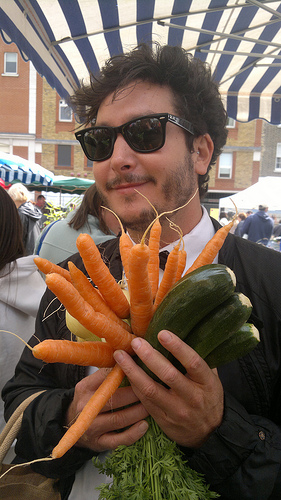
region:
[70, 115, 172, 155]
Large black sun glasses being worn and reflecting a crowd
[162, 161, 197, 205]
A patchy brown beard on a man's face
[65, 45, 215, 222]
Man with tousled brown hair and facial hair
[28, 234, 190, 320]
A group of large orange raw carrots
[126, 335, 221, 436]
Hand holding a number of different vegetables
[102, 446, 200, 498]
Leafy green heads of carrots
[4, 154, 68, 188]
White and blue canopy of a tent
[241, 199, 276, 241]
Man wearing a baseball hat and a blue sweater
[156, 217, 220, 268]
White under shirt being worn by a man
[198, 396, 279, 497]
Sleeve of a dark black jacket with a button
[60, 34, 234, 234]
the head of a man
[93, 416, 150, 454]
the finger of a man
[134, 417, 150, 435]
the finger nail of a man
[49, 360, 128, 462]
an orange carrot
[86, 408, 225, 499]
the stems of the carrots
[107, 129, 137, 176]
the nose of a man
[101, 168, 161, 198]
the mouth of a man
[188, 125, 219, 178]
the ear of a man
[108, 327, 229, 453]
the hand of a man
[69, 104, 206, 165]
a pair of sunglasses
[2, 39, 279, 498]
man holding vegetables at open air market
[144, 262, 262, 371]
green zucchinis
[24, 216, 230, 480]
fresh produce orange carrots with roots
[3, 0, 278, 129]
blue and white shade canopy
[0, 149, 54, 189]
blue and white striped canopy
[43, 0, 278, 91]
metal canopy frame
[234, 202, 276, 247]
man at outdoor market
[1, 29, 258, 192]
exterior brick wall of multistory building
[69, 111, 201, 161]
pair of sunglasses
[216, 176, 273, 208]
white shade canopy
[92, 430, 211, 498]
greens of a bunch of carrots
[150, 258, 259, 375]
three zucchinis squash in a hand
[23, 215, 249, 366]
bunch of orange carrots in a hand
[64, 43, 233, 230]
head of man with dark brown hair and beard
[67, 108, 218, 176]
dark eyeglasses on a man with a beard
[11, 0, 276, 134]
black and white stiped shade tent over a vendor's booth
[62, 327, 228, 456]
two hands holding fresh vegetables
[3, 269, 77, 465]
man's arm with black sleeve and handle of basket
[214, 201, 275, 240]
shoppers at an outdoor market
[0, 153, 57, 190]
white and dark green striped tent in outdoor market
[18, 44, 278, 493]
A man holds vegetables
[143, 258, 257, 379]
Three zucchini plants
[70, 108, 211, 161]
Black sunglasses cover the man's eyes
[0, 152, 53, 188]
A blue and white striped umbrella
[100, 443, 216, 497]
The green tops of carrots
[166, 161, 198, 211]
Sideburns on man's face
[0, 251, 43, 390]
A white sweatshirt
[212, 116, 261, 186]
A red and beige building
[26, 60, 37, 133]
A white stone border on a building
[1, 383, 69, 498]
The handle of a bag around man's arm